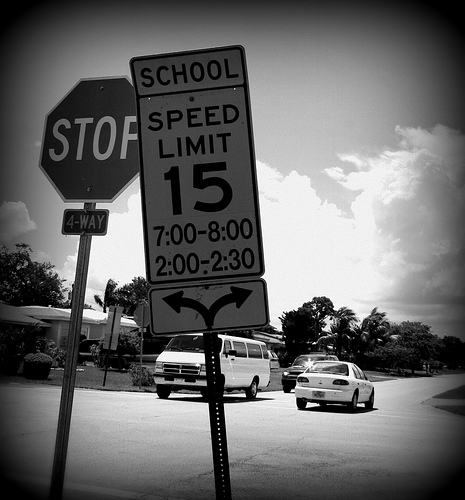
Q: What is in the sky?
A: Clouds.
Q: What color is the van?
A: White.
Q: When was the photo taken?
A: Daytime.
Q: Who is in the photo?
A: Nobody.